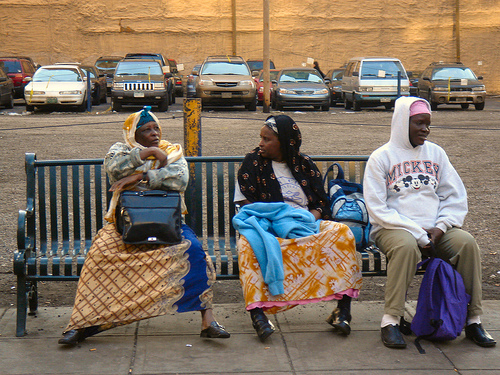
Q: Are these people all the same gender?
A: Yes, all the people are female.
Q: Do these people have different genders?
A: No, all the people are female.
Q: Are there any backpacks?
A: Yes, there is a backpack.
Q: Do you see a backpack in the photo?
A: Yes, there is a backpack.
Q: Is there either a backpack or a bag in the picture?
A: Yes, there is a backpack.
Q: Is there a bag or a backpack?
A: Yes, there is a backpack.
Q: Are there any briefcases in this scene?
A: No, there are no briefcases.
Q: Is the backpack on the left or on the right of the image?
A: The backpack is on the right of the image.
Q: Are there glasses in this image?
A: No, there are no glasses.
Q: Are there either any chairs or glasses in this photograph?
A: No, there are no glasses or chairs.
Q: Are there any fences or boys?
A: No, there are no boys or fences.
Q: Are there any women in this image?
A: Yes, there are women.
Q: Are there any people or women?
A: Yes, there are women.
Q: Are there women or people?
A: Yes, there are women.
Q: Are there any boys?
A: No, there are no boys.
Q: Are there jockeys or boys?
A: No, there are no boys or jockeys.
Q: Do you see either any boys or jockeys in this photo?
A: No, there are no boys or jockeys.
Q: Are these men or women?
A: These are women.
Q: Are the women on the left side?
A: Yes, the women are on the left of the image.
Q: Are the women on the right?
A: No, the women are on the left of the image.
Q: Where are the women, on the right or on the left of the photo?
A: The women are on the left of the image.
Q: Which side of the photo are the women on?
A: The women are on the left of the image.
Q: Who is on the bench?
A: The women are on the bench.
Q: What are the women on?
A: The women are on the bench.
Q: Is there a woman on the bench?
A: Yes, there are women on the bench.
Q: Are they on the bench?
A: Yes, the women are on the bench.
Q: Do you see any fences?
A: No, there are no fences.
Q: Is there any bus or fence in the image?
A: No, there are no fences or buses.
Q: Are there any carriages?
A: No, there are no carriages.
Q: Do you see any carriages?
A: No, there are no carriages.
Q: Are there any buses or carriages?
A: No, there are no carriages or buses.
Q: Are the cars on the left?
A: Yes, the cars are on the left of the image.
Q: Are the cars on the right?
A: No, the cars are on the left of the image.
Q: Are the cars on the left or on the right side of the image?
A: The cars are on the left of the image.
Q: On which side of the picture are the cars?
A: The cars are on the left of the image.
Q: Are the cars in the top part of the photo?
A: Yes, the cars are in the top of the image.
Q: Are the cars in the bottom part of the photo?
A: No, the cars are in the top of the image.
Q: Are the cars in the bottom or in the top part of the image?
A: The cars are in the top of the image.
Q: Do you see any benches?
A: Yes, there is a bench.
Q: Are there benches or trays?
A: Yes, there is a bench.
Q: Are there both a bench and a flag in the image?
A: No, there is a bench but no flags.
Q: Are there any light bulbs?
A: No, there are no light bulbs.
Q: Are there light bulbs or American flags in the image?
A: No, there are no light bulbs or American flags.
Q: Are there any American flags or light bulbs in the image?
A: No, there are no light bulbs or American flags.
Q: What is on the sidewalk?
A: The bench is on the sidewalk.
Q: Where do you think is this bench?
A: The bench is on the sidewalk.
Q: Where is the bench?
A: The bench is on the sidewalk.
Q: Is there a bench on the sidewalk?
A: Yes, there is a bench on the sidewalk.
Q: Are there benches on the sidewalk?
A: Yes, there is a bench on the sidewalk.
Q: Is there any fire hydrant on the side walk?
A: No, there is a bench on the side walk.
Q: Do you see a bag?
A: Yes, there is a bag.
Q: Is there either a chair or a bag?
A: Yes, there is a bag.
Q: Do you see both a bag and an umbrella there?
A: No, there is a bag but no umbrellas.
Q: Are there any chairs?
A: No, there are no chairs.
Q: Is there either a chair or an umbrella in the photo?
A: No, there are no chairs or umbrellas.